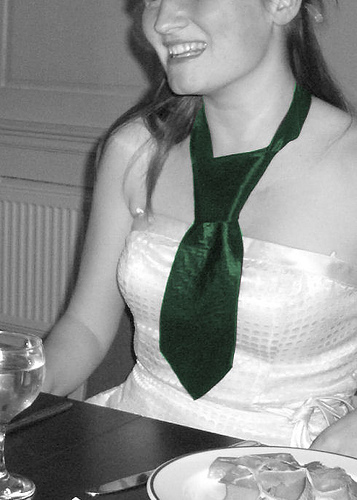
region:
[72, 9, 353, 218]
a woma nthat is smiling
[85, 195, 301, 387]
a woma wearing a dress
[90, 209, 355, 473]
woman wearing a white dress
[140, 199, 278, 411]
a woman wearing a tie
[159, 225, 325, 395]
a woman wearing a green tie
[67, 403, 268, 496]
a plate on the table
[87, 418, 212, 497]
a knife on the table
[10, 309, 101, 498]
a glass on teh table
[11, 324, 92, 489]
a wine glass on a table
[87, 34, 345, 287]
a woman with long hair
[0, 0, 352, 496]
A young woman sitting at the table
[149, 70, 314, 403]
Green tie around woman's neck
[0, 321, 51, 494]
A glass of water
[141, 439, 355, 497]
A round white plate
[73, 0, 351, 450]
Woman wearing a white dress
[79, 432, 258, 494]
A butter knife on the table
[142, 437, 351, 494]
Food is on a plate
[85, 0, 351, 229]
The young lady has long hair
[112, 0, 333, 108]
The woman is smiling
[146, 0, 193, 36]
Nose on woman's face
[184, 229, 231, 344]
a green tie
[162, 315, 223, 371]
the women is wearing a tie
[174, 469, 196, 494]
a plate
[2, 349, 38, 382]
a wine glass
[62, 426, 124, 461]
a table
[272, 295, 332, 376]
the women is wearing a dress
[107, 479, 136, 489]
a knife on the table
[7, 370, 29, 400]
liquid in the glass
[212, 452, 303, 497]
meat on the table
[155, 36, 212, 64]
the women is smiling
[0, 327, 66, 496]
Wine glass on a table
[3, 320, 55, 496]
Glass on a table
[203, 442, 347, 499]
Food on a plate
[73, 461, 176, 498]
Silverware on a table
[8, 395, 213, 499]
Table in front of a female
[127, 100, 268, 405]
Green tie on a woman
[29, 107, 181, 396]
Arm on a woman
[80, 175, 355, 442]
White dress on a woman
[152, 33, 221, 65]
Smile on a woman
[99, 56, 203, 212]
Hair falling on a woman's shoulder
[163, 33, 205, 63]
A woman's teeth in her mouth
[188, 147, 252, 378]
A green tie on a woman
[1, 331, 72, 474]
A small goblet on the table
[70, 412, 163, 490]
A dark brown table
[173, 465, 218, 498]
A white plate on the table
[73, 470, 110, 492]
A small knife on the table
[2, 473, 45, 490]
Bottom of the clear glass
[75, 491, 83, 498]
Handle of the butter knife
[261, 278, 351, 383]
The woman's white dress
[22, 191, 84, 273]
White wall behind the woman.